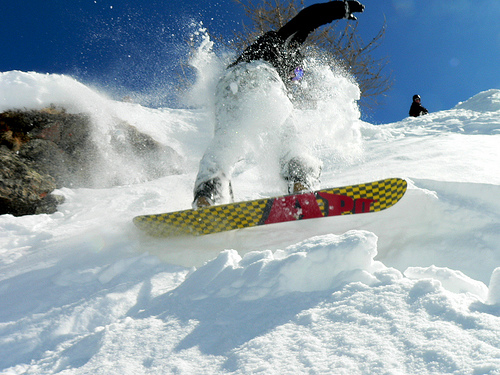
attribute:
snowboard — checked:
[144, 166, 452, 237]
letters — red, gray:
[270, 189, 364, 227]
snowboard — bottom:
[196, 180, 305, 228]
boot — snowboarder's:
[284, 160, 314, 202]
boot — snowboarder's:
[191, 172, 226, 211]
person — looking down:
[405, 87, 429, 119]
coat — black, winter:
[231, 30, 316, 85]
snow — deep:
[0, 57, 496, 372]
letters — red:
[258, 188, 372, 224]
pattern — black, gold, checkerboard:
[149, 178, 400, 235]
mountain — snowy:
[4, 67, 495, 323]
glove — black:
[348, 0, 364, 20]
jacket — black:
[224, 1, 349, 85]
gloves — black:
[342, 0, 363, 20]